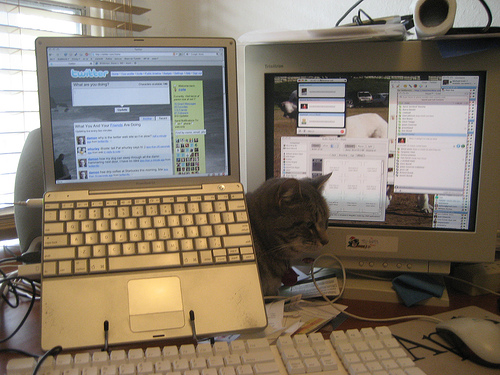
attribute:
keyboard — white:
[30, 323, 399, 369]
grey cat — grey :
[231, 166, 337, 305]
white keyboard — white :
[0, 327, 429, 373]